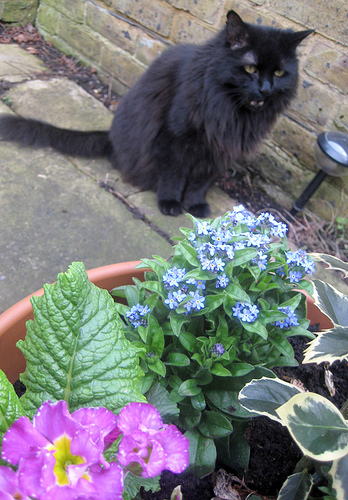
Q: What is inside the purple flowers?
A: Yellow interior.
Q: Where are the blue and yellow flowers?
A: In the pot.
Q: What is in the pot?
A: Plants.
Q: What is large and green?
A: Leaf.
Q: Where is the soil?
A: In the pot.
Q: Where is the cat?
A: On the patio.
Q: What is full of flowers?
A: Pot.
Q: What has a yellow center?
A: Flowers.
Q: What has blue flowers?
A: Plant.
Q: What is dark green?
A: Leaf.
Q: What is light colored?
A: Wall.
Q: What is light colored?
A: Bricks.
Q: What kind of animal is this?
A: Cat.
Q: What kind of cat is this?
A: Black long haired cat.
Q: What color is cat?
A: Black.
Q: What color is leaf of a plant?
A: Green.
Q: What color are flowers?
A: Purple.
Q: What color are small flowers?
A: Blue.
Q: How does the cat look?
A: Scary.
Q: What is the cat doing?
A: Sitting.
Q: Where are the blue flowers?
A: In the pot.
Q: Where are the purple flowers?
A: In the pot.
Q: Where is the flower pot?
A: On the ground.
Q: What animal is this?
A: Cat.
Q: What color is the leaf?
A: Green.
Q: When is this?
A: Daytime.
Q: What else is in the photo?
A: Wall.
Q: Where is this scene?
A: By the patio.